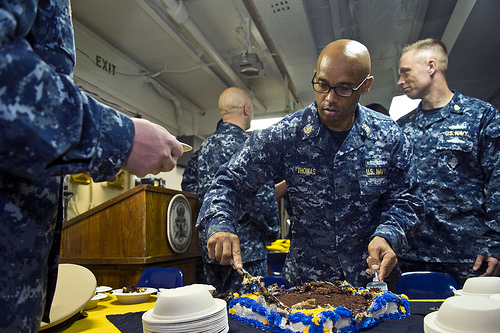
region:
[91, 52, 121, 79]
EXIT painted on the wall.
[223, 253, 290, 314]
A knife being used to cut a cake.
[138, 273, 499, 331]
3 stacks of upside-down paper bowls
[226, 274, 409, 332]
A mostly eaten decorated cake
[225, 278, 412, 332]
White, blue and yellow frosting on a cake.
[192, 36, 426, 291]
A Navy soldier named Thomas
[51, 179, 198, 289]
A podium with an emblem on the front.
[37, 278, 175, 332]
A yellow tablecloth.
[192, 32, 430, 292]
A man wearing black glasses.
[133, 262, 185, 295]
A blue chair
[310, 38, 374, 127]
a bald man wearing glasses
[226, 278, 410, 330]
a chocolate cake with colorful frosting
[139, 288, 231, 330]
a stack of paper bowl upside down on a table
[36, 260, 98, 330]
a white plate tilted upward on a table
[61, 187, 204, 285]
a wooden presentation desk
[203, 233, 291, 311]
a man cutting a cake with a knife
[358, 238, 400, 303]
man holding a metal spatula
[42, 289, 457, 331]
ellow and blue tablecloth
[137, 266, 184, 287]
top of a plastic blue chair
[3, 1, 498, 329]
navy men wearing uniforms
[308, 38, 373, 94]
THE MAN IS BALD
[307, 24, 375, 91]
THE MAN'S HEAD IS SHINY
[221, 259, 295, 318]
THE MAN IS CUTTING A CAKE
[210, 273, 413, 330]
THE CAKE IS ALMOST GONE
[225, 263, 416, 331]
THE CAKE HAS WHITE YELLOW AND BLUE ICING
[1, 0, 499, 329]
THE MEN ARE IN THE NAVY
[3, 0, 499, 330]
THE MEN ARE WEARING UNIFORMS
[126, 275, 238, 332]
THE BOWLS ARE PAPER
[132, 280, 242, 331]
THE BOWLS ARE WHITE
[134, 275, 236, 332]
THE BOWLS ARE STACKED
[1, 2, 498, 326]
navy men in uniform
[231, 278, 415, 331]
the cake is blue and yellow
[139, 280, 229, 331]
a stack of upside down bowls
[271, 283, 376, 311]
the middle of the cake is brown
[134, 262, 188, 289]
the chair is blue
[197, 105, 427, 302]
the man's uniform is blue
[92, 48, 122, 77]
the wall says exit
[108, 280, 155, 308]
a bowl with cake in it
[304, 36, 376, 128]
the man is wearing glasses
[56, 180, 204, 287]
the podium is brown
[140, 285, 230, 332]
A group of paper bowls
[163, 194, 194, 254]
A presidential seal on a podium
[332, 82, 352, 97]
The right glass frame of a man's glasses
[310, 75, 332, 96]
The left glass frame of a man's glasses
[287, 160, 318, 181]
The "Thomas" engraving of the man's vest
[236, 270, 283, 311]
A cutting knife in a cake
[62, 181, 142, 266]
The right side of a podium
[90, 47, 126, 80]
The word "Exit" on the side of a wall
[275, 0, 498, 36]
The top right portion of a ceiling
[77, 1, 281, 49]
The top left portion of a ceiling